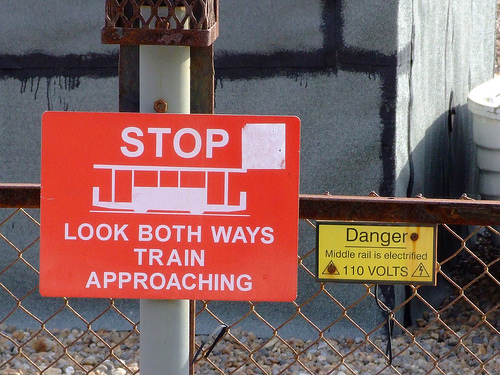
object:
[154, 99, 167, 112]
bolt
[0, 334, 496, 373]
gravel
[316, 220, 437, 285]
sign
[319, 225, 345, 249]
yellow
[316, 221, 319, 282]
black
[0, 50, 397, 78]
black marking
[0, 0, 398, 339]
sealer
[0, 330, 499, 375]
ground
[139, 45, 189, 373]
pole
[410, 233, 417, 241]
bolt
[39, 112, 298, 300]
sign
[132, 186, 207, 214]
train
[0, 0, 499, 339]
building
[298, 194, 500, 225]
rail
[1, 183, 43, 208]
rail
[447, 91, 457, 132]
circle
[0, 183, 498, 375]
cage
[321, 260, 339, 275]
marking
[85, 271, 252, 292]
writing